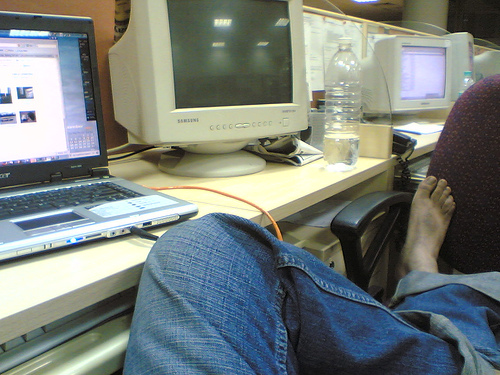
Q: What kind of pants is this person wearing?
A: Jeans.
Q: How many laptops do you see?
A: One.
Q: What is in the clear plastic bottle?
A: Water.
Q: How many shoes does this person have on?
A: None.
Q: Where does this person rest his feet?
A: In a chair.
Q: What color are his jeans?
A: Blue.